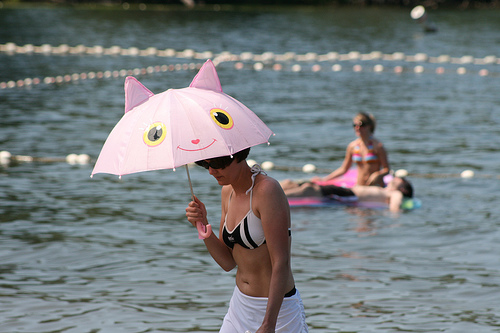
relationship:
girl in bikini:
[345, 101, 405, 238] [356, 150, 379, 186]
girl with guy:
[345, 101, 405, 238] [314, 190, 432, 217]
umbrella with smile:
[71, 65, 304, 149] [178, 141, 228, 166]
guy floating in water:
[314, 190, 432, 217] [245, 23, 379, 36]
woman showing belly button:
[177, 157, 323, 327] [236, 277, 283, 306]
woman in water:
[177, 157, 323, 327] [245, 23, 379, 36]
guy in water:
[314, 190, 432, 217] [245, 23, 379, 36]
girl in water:
[345, 101, 405, 238] [245, 23, 379, 36]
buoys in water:
[283, 53, 456, 82] [245, 23, 379, 36]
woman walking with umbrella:
[177, 157, 323, 327] [71, 65, 304, 149]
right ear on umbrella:
[183, 63, 239, 96] [71, 65, 304, 149]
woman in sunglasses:
[177, 157, 323, 327] [192, 159, 253, 174]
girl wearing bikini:
[345, 101, 405, 238] [356, 150, 379, 186]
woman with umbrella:
[177, 157, 323, 327] [71, 65, 304, 149]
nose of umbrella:
[180, 129, 206, 149] [71, 65, 304, 149]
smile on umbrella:
[178, 141, 228, 166] [71, 65, 304, 149]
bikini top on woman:
[212, 203, 304, 253] [177, 157, 323, 327]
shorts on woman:
[218, 293, 311, 325] [177, 157, 323, 327]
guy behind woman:
[314, 190, 432, 217] [177, 157, 323, 327]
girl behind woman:
[345, 101, 405, 238] [177, 157, 323, 327]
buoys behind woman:
[283, 53, 456, 82] [177, 157, 323, 327]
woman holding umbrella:
[177, 157, 323, 327] [71, 65, 304, 149]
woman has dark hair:
[177, 157, 323, 327] [235, 153, 249, 158]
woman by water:
[177, 157, 323, 327] [245, 23, 379, 36]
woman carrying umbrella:
[177, 157, 323, 327] [71, 65, 304, 149]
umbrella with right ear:
[71, 65, 304, 149] [183, 63, 239, 96]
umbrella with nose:
[71, 65, 304, 149] [180, 129, 206, 149]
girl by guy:
[345, 101, 405, 238] [314, 190, 432, 217]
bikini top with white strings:
[212, 203, 304, 253] [248, 164, 262, 222]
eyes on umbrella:
[143, 112, 242, 124] [71, 65, 304, 149]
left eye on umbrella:
[123, 114, 185, 149] [71, 65, 304, 149]